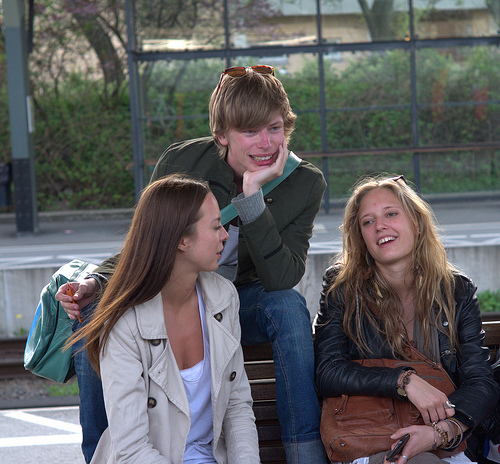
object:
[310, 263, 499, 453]
jacket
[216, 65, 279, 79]
sunglasses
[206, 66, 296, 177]
head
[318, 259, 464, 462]
bag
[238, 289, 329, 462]
leg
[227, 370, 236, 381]
button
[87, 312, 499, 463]
bench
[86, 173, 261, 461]
girl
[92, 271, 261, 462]
pea-coat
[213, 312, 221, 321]
button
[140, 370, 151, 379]
button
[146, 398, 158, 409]
button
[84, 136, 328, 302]
jacket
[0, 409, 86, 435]
lines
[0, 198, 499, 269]
street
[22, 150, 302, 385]
bag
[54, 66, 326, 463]
boy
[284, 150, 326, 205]
shoulder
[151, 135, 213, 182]
shoulder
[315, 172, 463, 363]
hair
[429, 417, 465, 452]
bracelets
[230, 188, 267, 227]
cuff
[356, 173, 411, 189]
sunglasses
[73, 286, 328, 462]
jeans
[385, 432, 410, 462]
phone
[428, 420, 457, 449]
wrist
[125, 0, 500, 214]
fence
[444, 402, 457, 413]
silver ring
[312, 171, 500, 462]
girl